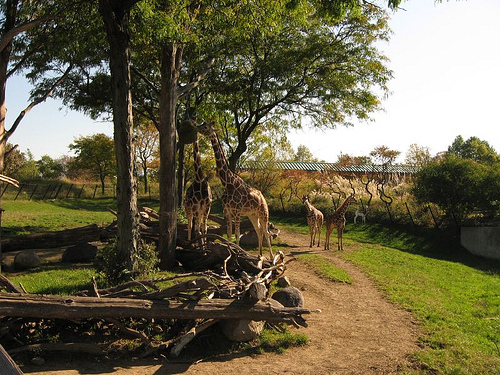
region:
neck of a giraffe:
[329, 189, 357, 211]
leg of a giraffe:
[259, 199, 267, 264]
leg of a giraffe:
[242, 232, 264, 262]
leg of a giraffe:
[227, 213, 245, 265]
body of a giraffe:
[215, 172, 280, 233]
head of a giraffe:
[189, 115, 224, 139]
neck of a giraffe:
[209, 135, 241, 182]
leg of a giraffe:
[190, 201, 221, 255]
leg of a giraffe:
[182, 215, 197, 260]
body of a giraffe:
[180, 166, 221, 218]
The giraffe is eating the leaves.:
[178, 105, 225, 147]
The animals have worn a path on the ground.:
[266, 233, 426, 371]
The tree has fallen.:
[1, 264, 330, 351]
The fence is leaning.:
[16, 174, 118, 211]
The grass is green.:
[421, 268, 486, 338]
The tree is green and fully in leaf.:
[414, 117, 489, 276]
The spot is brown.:
[217, 168, 228, 180]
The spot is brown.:
[225, 182, 234, 192]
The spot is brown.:
[236, 184, 248, 199]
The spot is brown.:
[252, 195, 264, 208]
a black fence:
[4, 182, 118, 197]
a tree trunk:
[107, 47, 141, 267]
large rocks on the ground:
[67, 247, 102, 261]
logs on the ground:
[18, 278, 265, 342]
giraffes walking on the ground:
[173, 116, 358, 253]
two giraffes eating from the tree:
[183, 119, 273, 249]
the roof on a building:
[233, 160, 442, 174]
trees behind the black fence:
[420, 140, 482, 220]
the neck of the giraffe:
[206, 140, 231, 172]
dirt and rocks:
[316, 296, 372, 364]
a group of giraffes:
[161, 103, 373, 264]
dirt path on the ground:
[0, 218, 445, 373]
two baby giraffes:
[293, 175, 366, 252]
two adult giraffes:
[170, 92, 281, 269]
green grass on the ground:
[352, 237, 497, 374]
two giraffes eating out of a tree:
[168, 101, 283, 263]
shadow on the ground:
[287, 240, 319, 257]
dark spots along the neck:
[210, 138, 232, 183]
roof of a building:
[208, 150, 428, 182]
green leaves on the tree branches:
[12, 0, 402, 147]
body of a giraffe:
[220, 171, 282, 226]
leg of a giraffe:
[265, 225, 283, 280]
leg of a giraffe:
[246, 216, 276, 278]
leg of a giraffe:
[212, 218, 237, 282]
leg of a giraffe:
[196, 218, 213, 262]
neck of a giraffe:
[330, 199, 351, 219]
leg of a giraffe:
[332, 231, 350, 261]